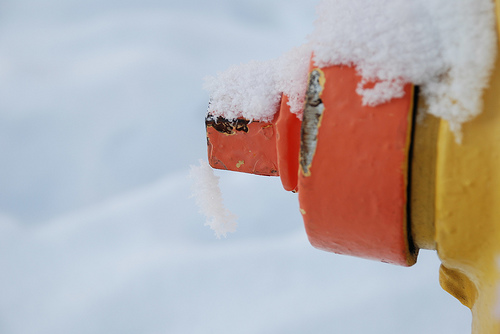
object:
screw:
[205, 57, 295, 191]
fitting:
[297, 0, 418, 264]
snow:
[193, 156, 229, 246]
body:
[414, 0, 500, 328]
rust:
[206, 112, 243, 138]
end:
[206, 64, 277, 180]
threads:
[407, 80, 431, 250]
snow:
[190, 0, 489, 232]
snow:
[205, 0, 500, 138]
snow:
[0, 270, 80, 324]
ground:
[0, 3, 472, 333]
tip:
[205, 45, 315, 195]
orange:
[205, 57, 415, 268]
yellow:
[413, 0, 500, 328]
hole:
[206, 118, 248, 134]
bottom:
[425, 267, 494, 332]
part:
[205, 45, 315, 195]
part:
[303, 62, 409, 272]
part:
[411, 54, 500, 131]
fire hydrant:
[199, 0, 500, 328]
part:
[434, 268, 497, 330]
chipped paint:
[302, 69, 328, 186]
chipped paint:
[204, 114, 251, 136]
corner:
[435, 263, 478, 311]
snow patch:
[0, 0, 328, 112]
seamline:
[404, 70, 419, 260]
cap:
[202, 0, 415, 264]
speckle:
[313, 94, 326, 128]